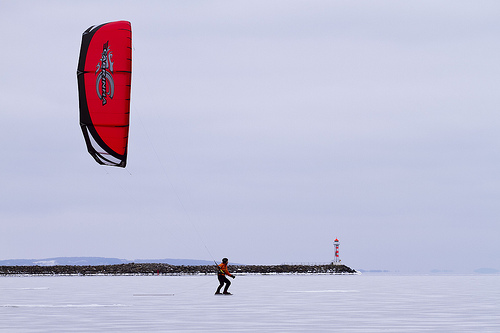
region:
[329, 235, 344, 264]
a red and white building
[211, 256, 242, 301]
a man in bright orange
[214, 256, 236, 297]
a man on the water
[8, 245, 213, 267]
some land in the distance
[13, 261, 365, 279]
a long rock jetty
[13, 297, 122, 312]
a small wave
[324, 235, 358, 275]
a lighthouse at the end of the jetty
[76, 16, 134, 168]
a large red and black kite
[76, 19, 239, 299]
a man kite boarding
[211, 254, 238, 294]
one man gliding on ice covered ground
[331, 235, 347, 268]
one bright red lighthouse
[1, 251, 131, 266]
snow covered mountains with gray sky in background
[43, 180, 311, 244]
section of cloudless blue sky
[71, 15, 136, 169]
one red oblong parasail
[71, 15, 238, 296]
one man parasailing on ice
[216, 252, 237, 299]
man dressed in red jacket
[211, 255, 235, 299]
one man wearing dark pants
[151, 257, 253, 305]
man sliding on ice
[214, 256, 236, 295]
one man with both knees bent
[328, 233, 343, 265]
a red and white lighthouse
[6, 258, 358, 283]
a rocky strip leading to a lighthouse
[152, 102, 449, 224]
a gray overcast sky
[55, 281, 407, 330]
a calm body of water with few small waves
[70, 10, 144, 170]
an orange and black parachute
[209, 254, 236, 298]
a man atached to a parachute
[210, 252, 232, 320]
a man wearing orange and black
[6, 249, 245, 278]
the shore in the distance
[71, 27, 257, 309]
a man parasailing into water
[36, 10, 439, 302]
a dreary overcast day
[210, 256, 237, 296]
A waterskier in red.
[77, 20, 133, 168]
A red and black parachute.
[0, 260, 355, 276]
A rocky peninsula.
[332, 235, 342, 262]
A red and white lighthouse.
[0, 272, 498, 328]
A large body of water.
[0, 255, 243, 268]
A distant mountain range.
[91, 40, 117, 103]
A black and silver logo.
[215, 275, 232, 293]
A human pair of legs.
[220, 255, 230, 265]
A black safety helmet.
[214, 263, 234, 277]
A red colored jacket.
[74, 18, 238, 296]
A red parachute is pulling the man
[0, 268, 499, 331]
The water has turned to ice.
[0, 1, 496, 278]
The sky is mostly cloudy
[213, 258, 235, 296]
He is dressed for cold weather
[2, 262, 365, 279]
Rocks jetting out into the water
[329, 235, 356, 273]
Light house sits at the end of the rocks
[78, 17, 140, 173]
The parachute is black, red and gray.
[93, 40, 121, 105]
Logo on the parachute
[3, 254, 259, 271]
Mountains in the background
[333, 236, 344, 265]
The lighthouse is brightly colored.